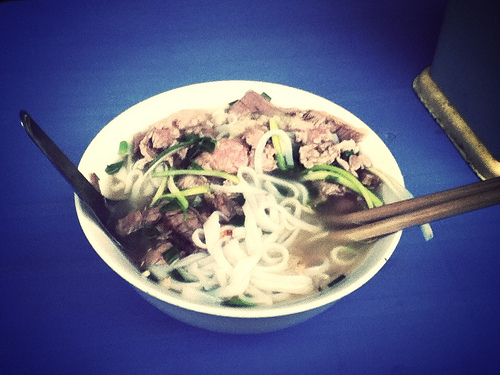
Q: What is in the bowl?
A: Noodles.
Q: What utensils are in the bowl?
A: Chopsticks.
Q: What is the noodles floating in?
A: Broth.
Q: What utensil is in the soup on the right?
A: Chopsticks.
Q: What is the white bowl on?
A: Blue table.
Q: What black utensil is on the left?
A: Spoon.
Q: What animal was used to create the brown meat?
A: Cow.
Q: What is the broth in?
A: White bowl.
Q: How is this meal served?
A: In a bowl.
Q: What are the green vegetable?
A: Scallions.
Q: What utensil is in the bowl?
A: Chopsticks.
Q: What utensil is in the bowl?
A: Black spoon.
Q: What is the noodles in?
A: A white bowl.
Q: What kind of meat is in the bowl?
A: Chicken.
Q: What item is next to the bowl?
A: Tarnished brass metal piece.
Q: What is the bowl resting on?
A: Blue table.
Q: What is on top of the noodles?
A: Leeks.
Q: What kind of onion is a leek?
A: Green onion.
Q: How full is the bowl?
A: Completley full.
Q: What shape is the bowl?
A: Bowl is round.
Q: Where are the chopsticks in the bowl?
A: The right.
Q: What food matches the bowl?
A: Noodles.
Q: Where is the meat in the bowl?
A: Top.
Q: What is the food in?
A: White bowl.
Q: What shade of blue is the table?
A: Navy blue.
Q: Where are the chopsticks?
A: On the right side of the bowl.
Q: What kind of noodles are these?
A: Rice.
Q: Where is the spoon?
A: On the left.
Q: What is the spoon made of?
A: Black plastic.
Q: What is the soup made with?
A: Broth.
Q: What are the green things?
A: Green onions.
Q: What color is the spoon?
A: Black.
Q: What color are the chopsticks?
A: Brown.